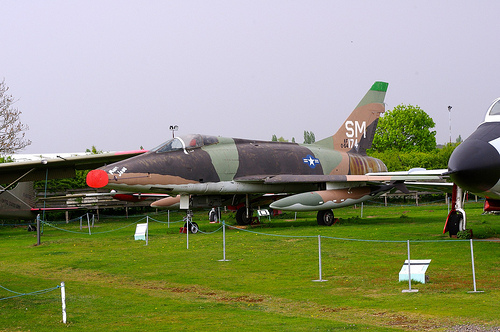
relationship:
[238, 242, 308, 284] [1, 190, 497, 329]
patch of grass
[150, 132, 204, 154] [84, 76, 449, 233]
canopy of plane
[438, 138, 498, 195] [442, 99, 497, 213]
nose of aircraft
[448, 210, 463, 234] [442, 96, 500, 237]
wheel of aircraft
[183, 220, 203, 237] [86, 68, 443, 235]
front wheel of plane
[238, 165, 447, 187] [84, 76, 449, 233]
wing of plane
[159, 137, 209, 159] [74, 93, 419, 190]
cockpit of aircraft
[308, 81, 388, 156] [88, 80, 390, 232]
tail of aircraft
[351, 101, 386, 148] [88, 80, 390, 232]
rudder of aircraft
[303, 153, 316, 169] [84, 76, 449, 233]
circle on plane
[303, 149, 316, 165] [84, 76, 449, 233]
star on plane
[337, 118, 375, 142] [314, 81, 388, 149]
sm mentioned on tail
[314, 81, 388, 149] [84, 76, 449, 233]
tail of plane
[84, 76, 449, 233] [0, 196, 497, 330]
plane on ground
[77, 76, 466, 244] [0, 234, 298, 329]
plane on ground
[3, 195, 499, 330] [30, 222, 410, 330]
field covered in grass